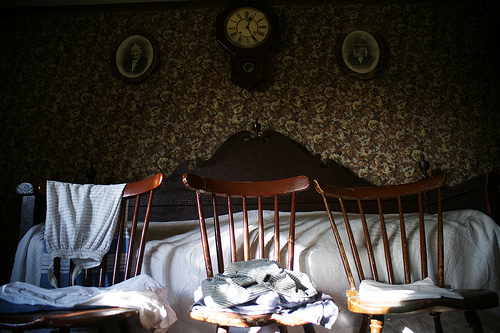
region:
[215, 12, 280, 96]
old clock hanging on a wall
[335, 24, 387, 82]
oval framed picture of a man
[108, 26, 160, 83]
oval shaped framed picture of a lady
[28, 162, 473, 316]
three wooden chairs in a row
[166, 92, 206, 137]
gold and brown floral wall paper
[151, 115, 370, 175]
fancy wooden head board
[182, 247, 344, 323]
pile of pajamas on a chair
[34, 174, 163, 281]
striped pajamas hanging on a chair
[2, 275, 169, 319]
white clothing on a chair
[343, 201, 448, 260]
wooden spindles on a chair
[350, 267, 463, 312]
folded clothes on a chair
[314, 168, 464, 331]
chair on the right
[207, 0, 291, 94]
clock above the bed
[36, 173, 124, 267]
pajamas over a chair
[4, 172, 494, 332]
three chairs near the bed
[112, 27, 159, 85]
a oval picture frame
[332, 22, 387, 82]
an oval picture frame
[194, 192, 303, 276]
seven wooded rods at the back of a chair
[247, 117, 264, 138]
wooden ball at the head of the headboard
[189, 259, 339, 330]
a stack of white clothing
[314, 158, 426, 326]
A wooden chair is visible.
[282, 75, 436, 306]
A wooden chair is visible.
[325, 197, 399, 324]
A wooden chair is visible.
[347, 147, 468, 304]
A wooden chair is visible.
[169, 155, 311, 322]
Wooden chair no arms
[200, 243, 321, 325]
Pile of clothing on chair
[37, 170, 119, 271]
Pair of pants hanging on back of chair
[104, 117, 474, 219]
Wooden headboard of the bed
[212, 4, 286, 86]
Clock hanging on the wall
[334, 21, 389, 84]
Circular portrait on the wall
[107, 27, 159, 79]
Woman's portrait on the wall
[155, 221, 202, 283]
White comforter on the bed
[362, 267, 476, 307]
Dress shirt laying on chair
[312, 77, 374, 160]
Abstract print wall paper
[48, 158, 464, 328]
three wooden chairs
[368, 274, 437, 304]
a white towel in chair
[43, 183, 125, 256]
a white striped garment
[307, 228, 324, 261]
a white bedspread on the bed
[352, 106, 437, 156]
floral wall paper on the wall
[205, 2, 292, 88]
an old analog clock on the wall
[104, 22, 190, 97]
a black and white photograph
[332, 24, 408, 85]
the photo a man in a pilot uniform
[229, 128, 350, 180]
a dark cherry wood head board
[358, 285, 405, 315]
light reflecting on the chair